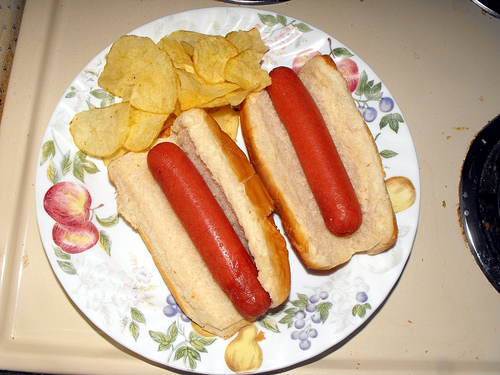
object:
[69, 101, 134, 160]
chips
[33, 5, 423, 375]
plate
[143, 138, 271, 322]
weiner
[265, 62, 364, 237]
dog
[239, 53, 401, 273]
bun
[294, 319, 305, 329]
grapes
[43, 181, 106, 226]
apple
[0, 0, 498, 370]
table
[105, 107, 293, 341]
hotdogs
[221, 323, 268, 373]
pear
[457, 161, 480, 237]
edge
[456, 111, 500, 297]
burner